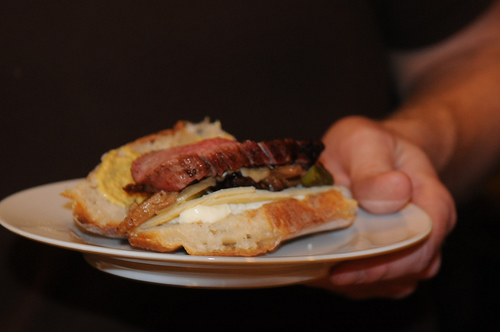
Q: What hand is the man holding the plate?
A: Left.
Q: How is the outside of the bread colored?
A: Golden brown.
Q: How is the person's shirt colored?
A: Black.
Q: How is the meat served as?
A: Sliced.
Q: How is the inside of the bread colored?
A: White.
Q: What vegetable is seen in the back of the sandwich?
A: Pickle.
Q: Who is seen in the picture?
A: A man's body.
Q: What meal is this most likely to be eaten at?
A: Lunch.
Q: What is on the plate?
A: A sandwich.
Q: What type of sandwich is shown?
A: Beef.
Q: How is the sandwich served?
A: Open faced.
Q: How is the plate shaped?
A: Roundly.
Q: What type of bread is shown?
A: French.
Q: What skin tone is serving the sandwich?
A: White.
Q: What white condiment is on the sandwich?
A: Mayonnaise.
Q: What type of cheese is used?
A: White.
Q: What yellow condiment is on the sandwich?
A: Mustard.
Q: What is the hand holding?
A: Plate.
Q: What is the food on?
A: Plate.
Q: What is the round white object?
A: Plate.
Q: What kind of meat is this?
A: Sausage.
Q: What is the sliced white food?
A: Cheese.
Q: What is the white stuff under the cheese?
A: Mayonnaise.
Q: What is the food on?
A: A plate.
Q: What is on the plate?
A: Food.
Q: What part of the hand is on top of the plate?
A: Thumb.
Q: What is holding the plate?
A: A hand.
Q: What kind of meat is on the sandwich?
A: Grilled hot sausage.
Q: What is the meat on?
A: Bread.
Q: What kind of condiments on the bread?
A: Mayonnaise.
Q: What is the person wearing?
A: Black shirt.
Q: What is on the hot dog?
A: Onions.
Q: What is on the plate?
A: A sandwich.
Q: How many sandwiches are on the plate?
A: One.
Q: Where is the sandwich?
A: On a plate.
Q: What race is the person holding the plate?
A: White.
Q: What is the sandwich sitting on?
A: A place.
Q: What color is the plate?
A: White.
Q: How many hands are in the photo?
A: One.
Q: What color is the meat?
A: Brown.